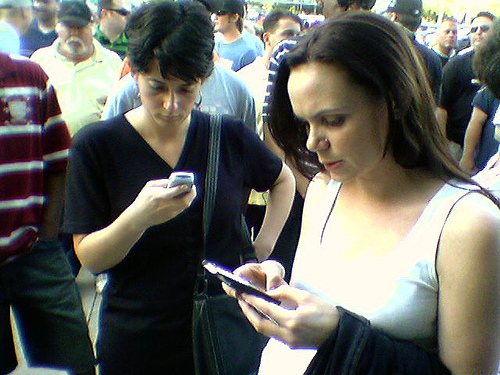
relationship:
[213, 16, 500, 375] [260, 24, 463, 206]
person has head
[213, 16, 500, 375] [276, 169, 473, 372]
person wearing tank top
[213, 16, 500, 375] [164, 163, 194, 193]
person dialing phone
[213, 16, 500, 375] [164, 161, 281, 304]
person on phones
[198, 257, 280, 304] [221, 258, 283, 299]
phone on hand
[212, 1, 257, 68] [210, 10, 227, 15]
man with sunglasses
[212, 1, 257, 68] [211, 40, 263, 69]
man wearing blue shirt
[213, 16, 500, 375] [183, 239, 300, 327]
person looking at phone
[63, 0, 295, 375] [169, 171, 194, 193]
person holding phone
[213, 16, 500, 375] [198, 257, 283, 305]
person holding phone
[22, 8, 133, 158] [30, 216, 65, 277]
man has hand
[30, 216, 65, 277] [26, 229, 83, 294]
hand in pocket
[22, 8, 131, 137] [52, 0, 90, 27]
man wearing cap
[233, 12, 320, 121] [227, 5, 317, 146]
man has shirt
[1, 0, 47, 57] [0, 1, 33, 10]
man wearing cap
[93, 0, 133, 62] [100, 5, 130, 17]
man wearing sunglasses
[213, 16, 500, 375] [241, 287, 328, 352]
person has hand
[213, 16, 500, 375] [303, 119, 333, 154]
person has nose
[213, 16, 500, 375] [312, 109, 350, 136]
person has eye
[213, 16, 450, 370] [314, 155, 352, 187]
person has chin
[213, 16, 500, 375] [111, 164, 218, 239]
person has hand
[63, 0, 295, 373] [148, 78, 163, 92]
person has eye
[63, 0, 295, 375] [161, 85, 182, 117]
person has nose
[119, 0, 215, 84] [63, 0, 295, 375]
hair of person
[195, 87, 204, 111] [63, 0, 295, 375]
earring on person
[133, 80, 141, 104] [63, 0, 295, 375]
earring on person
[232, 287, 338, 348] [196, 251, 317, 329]
hand on phone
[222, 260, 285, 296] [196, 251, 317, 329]
hand on phone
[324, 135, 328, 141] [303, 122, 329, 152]
mole on nose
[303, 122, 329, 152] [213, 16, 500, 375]
nose on person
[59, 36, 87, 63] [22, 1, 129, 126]
facial hair on man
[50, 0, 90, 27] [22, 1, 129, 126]
cap on man